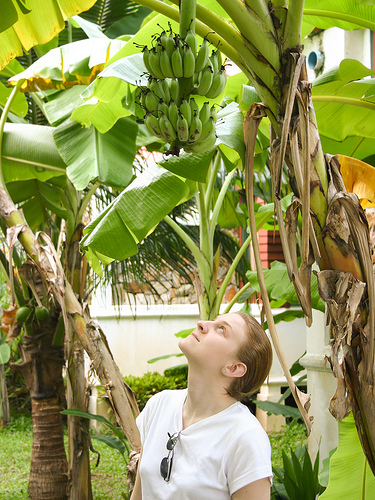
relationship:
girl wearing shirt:
[124, 309, 273, 496] [132, 386, 277, 497]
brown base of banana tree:
[16, 351, 71, 497] [3, 0, 291, 497]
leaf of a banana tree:
[90, 158, 235, 260] [171, 4, 374, 490]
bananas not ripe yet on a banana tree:
[170, 43, 186, 81] [171, 4, 374, 485]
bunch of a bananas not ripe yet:
[119, 98, 234, 145] [170, 43, 186, 81]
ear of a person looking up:
[220, 359, 247, 381] [222, 363, 250, 384]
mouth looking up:
[188, 333, 205, 347] [180, 325, 205, 354]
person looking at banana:
[128, 310, 276, 500] [169, 46, 186, 82]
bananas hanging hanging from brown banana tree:
[117, 1, 242, 167] [273, 181, 375, 478]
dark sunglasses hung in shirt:
[158, 429, 180, 479] [135, 386, 277, 497]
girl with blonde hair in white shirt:
[124, 309, 273, 496] [135, 386, 277, 497]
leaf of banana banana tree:
[82, 143, 230, 260] [65, 5, 93, 498]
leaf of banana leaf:
[82, 143, 230, 260] [82, 143, 230, 260]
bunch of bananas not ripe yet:
[135, 23, 230, 153] [127, 1, 235, 163]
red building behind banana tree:
[180, 8, 368, 317] [171, 4, 374, 485]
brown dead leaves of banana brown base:
[1, 58, 372, 425] [24, 351, 71, 497]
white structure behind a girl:
[70, 299, 373, 487] [124, 309, 273, 496]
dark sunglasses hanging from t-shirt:
[158, 429, 180, 479] [128, 387, 291, 496]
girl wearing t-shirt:
[124, 309, 273, 496] [129, 386, 272, 497]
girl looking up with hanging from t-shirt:
[119, 303, 280, 496] [157, 429, 180, 479]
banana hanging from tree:
[107, 13, 244, 160] [127, 5, 346, 249]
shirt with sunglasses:
[135, 386, 277, 497] [152, 423, 185, 489]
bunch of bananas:
[135, 23, 230, 153] [126, 22, 242, 157]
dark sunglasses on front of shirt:
[158, 429, 180, 479] [132, 386, 277, 497]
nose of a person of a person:
[191, 318, 210, 335] [116, 312, 281, 498]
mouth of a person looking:
[182, 326, 205, 346] [118, 303, 289, 493]